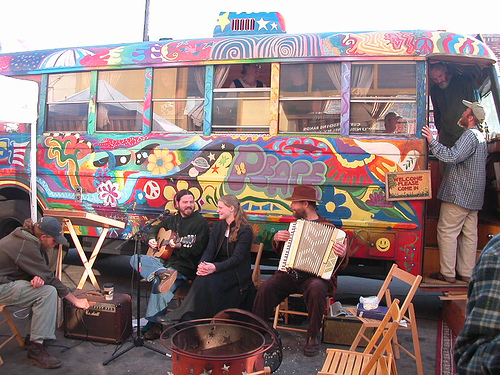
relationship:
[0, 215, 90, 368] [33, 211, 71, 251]
man wearing cap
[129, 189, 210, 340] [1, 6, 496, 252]
man sitting by bus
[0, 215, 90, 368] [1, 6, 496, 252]
man sitting by bus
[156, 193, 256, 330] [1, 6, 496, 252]
person sitting by bus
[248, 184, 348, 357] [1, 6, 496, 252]
man sitting by bus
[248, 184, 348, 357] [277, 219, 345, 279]
man playing instrument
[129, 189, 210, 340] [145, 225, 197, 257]
man playing guitar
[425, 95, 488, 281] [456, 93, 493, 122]
man wearing hat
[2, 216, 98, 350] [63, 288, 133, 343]
man fiddling with amp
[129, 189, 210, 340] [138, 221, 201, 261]
man playing guitar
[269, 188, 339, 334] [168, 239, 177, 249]
man in hand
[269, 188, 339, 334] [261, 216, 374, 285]
man playing accordion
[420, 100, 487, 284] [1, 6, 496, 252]
man walking into bus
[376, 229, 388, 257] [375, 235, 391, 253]
smiley face on sticker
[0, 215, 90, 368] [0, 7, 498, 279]
man near bus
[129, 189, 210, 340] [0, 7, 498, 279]
man near bus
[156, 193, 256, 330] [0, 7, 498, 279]
person near bus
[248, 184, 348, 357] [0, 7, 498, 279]
man near bus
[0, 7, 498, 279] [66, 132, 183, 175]
bus painted with designs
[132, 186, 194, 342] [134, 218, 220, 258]
man playing guitar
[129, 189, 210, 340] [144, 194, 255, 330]
man looking at person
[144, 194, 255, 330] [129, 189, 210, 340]
person seated beside man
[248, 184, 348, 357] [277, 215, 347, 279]
man playing accordian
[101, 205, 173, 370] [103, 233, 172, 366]
microphone stand on microphone stand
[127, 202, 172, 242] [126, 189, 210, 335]
microphone in front of man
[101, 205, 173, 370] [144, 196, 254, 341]
microphone stand in front of woman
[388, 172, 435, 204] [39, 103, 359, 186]
sign hung on bus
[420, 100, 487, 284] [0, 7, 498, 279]
man standing bus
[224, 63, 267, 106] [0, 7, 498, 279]
woman standing in bus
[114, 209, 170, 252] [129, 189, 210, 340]
microphone on man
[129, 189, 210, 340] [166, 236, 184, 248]
man has hand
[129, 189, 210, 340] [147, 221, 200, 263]
man holding guitar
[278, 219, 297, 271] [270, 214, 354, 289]
keys on accordion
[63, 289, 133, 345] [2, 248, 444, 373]
amp on ground